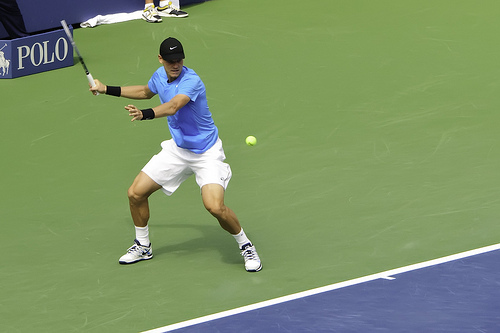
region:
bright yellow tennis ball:
[229, 117, 276, 164]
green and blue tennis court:
[144, 58, 472, 320]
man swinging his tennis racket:
[37, 15, 301, 282]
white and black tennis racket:
[42, 16, 134, 126]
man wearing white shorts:
[88, 29, 279, 286]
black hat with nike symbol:
[139, 31, 196, 79]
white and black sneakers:
[123, 235, 175, 285]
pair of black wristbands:
[88, 73, 176, 144]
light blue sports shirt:
[120, 43, 241, 159]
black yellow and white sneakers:
[132, 1, 197, 34]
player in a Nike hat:
[67, 30, 281, 277]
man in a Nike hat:
[72, 28, 267, 281]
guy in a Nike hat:
[78, 25, 265, 276]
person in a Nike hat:
[86, 32, 264, 277]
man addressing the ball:
[27, 14, 274, 284]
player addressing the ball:
[44, 11, 289, 282]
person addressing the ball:
[54, 16, 272, 275]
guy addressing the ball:
[30, 11, 275, 277]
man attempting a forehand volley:
[52, 17, 281, 282]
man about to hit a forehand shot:
[50, 11, 293, 279]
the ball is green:
[204, 91, 257, 156]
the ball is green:
[211, 106, 296, 208]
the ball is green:
[240, 133, 340, 239]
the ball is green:
[221, 106, 273, 187]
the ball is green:
[176, 76, 303, 227]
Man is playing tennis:
[108, 22, 244, 292]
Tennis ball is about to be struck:
[222, 112, 277, 166]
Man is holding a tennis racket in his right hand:
[47, 8, 125, 116]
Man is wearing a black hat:
[141, 26, 221, 83]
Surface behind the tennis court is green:
[274, 25, 491, 230]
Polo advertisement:
[4, 30, 84, 72]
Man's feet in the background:
[135, 1, 199, 23]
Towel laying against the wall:
[74, 10, 154, 25]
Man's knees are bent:
[111, 164, 243, 236]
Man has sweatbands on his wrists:
[97, 68, 157, 126]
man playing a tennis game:
[45, 14, 265, 286]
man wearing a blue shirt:
[115, 20, 221, 165]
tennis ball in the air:
[233, 114, 265, 156]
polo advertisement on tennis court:
[14, 39, 72, 66]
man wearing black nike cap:
[143, 31, 190, 85]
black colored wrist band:
[103, 80, 123, 100]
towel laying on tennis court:
[77, 8, 144, 28]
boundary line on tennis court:
[154, 232, 496, 328]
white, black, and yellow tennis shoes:
[140, 7, 190, 24]